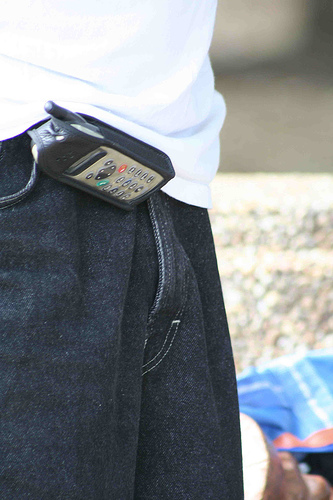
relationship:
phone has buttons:
[26, 98, 181, 216] [124, 166, 156, 183]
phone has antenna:
[26, 98, 181, 216] [37, 97, 86, 122]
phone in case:
[26, 98, 181, 216] [26, 118, 181, 208]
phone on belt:
[26, 98, 181, 216] [22, 126, 29, 143]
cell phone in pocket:
[26, 98, 181, 216] [0, 144, 47, 214]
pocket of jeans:
[0, 144, 47, 214] [5, 126, 248, 499]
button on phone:
[116, 162, 130, 174] [26, 98, 181, 216]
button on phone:
[94, 180, 110, 190] [26, 98, 181, 216]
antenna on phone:
[37, 97, 86, 122] [26, 98, 181, 216]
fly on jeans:
[146, 198, 177, 326] [5, 126, 248, 499]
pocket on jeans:
[0, 144, 47, 214] [5, 126, 248, 499]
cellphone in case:
[26, 98, 181, 216] [26, 118, 181, 208]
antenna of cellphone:
[37, 97, 86, 122] [26, 98, 181, 216]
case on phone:
[26, 118, 181, 208] [26, 98, 181, 216]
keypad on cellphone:
[78, 157, 157, 199] [26, 98, 181, 216]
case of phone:
[26, 118, 181, 208] [26, 98, 181, 216]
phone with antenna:
[26, 98, 181, 216] [37, 97, 86, 122]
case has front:
[26, 118, 181, 208] [65, 151, 159, 205]